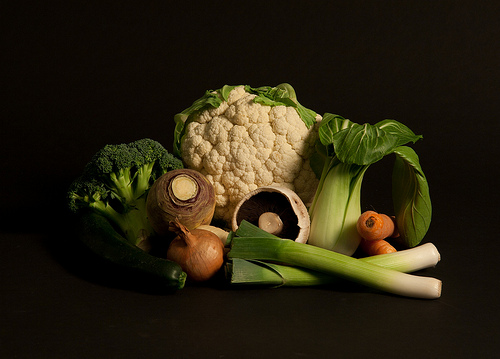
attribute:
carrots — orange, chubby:
[356, 208, 398, 255]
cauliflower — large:
[172, 87, 332, 195]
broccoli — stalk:
[62, 135, 184, 246]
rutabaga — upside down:
[142, 165, 219, 242]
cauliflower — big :
[183, 82, 311, 219]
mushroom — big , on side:
[230, 183, 312, 250]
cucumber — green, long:
[23, 172, 190, 294]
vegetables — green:
[221, 219, 443, 299]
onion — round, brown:
[164, 219, 224, 279]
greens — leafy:
[305, 112, 433, 256]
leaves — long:
[322, 117, 417, 165]